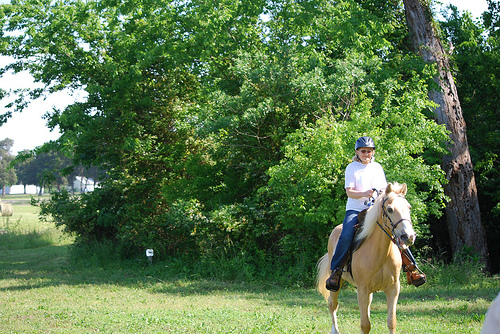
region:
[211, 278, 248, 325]
part of a ground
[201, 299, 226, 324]
part of a ground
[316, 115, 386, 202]
this is a man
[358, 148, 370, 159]
the man is light skinned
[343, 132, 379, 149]
this is a helmet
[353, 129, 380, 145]
the helmet is blue in color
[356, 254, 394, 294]
the horse is brown in color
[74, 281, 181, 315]
this is a grass area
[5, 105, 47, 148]
this is the sky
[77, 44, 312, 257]
these are green trees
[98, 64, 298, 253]
the tree has lots of foilage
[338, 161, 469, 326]
this is horse rider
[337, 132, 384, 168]
the person has a helmet on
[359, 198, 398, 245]
the horse mane is white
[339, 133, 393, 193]
this is a man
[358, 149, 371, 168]
the man is light skinned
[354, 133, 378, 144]
this is a helmet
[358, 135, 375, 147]
the helmet is blue in color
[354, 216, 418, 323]
this is a horse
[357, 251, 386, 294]
the horse is brown in color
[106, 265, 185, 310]
this is a grass area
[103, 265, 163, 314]
the grass is green in color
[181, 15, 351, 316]
this is a tree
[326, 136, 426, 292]
a woman riding a horse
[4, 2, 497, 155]
blue sky visible through the trees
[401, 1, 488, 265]
a grey brown tree trunk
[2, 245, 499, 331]
a mown grassy area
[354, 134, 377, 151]
a helmet on a woman's head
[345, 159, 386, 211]
a white shirt on a woman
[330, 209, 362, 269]
blue pants on a woman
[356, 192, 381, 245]
the white mane of a horse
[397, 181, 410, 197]
the ear of a horse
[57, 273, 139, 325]
Large patch of grass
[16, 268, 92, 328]
Large patch of grass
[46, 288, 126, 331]
Large patch of grass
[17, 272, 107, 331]
Large patch of grass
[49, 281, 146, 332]
Large patch of grass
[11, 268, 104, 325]
Large patch of grass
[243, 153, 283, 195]
green leaves on the tree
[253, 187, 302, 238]
green leaves on the tree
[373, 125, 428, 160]
green leaves on the tree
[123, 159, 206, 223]
green leaves on the tree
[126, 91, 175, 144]
green leaves on the tree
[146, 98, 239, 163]
green leaves on the tree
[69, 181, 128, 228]
green leaves on the tree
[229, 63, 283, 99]
green leaves on the tree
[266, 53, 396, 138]
green leaves on the tree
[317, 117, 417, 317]
tan horse ridden by rider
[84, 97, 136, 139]
green leaves in brown tree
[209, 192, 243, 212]
green leaves in brown tree